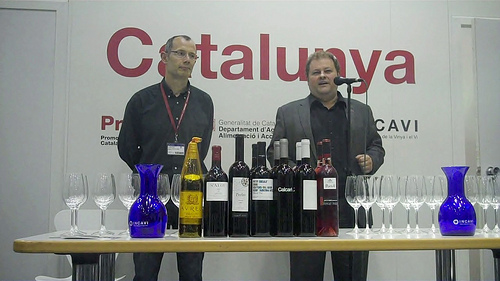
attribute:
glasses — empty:
[338, 176, 496, 246]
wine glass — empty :
[345, 175, 367, 235]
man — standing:
[263, 50, 386, 280]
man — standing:
[113, 32, 217, 279]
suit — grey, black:
[276, 93, 378, 278]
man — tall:
[134, 2, 219, 150]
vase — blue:
[125, 161, 169, 238]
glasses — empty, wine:
[337, 164, 476, 235]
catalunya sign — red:
[66, 2, 451, 174]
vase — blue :
[121, 160, 171, 237]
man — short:
[281, 53, 373, 159]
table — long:
[11, 218, 497, 254]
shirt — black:
[115, 71, 217, 193]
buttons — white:
[162, 90, 173, 100]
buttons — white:
[179, 94, 191, 101]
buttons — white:
[173, 97, 181, 107]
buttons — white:
[169, 115, 184, 123]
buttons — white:
[169, 161, 182, 171]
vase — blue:
[436, 162, 479, 237]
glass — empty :
[61, 171, 88, 238]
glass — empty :
[91, 172, 121, 237]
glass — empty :
[116, 170, 141, 237]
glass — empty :
[344, 173, 367, 237]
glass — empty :
[382, 175, 402, 235]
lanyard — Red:
[157, 83, 189, 160]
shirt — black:
[307, 96, 353, 176]